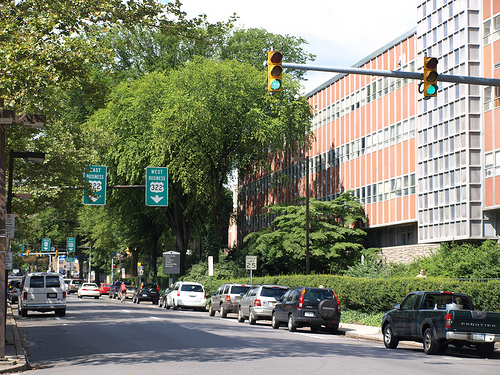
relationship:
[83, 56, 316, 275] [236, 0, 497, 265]
trees are near building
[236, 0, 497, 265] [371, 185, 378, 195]
building has windows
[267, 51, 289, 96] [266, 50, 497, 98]
street sign hanging from pole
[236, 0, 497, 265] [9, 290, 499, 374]
building on side of street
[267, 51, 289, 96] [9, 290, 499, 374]
street sign on left side of street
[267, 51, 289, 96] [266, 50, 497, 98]
street sign on pole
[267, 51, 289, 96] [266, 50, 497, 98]
street sign attached to pole